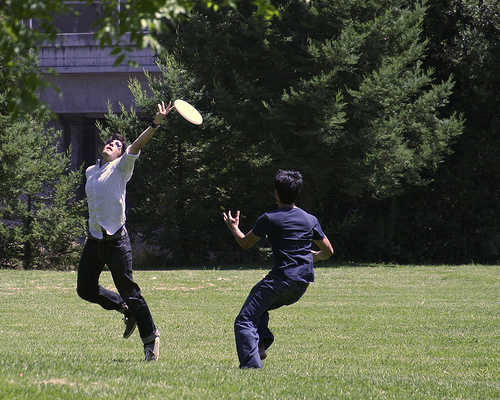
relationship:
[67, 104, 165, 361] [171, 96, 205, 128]
man about to catch a frisbee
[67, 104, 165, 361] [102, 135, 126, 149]
man wearing sunglasses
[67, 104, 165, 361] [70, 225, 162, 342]
man wearing pants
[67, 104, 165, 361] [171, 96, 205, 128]
man playing frisbee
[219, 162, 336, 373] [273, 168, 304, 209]
man with black hair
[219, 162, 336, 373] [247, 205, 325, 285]
man wearing a black shirt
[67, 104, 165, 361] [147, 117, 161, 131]
man wearing a black watch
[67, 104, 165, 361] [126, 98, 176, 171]
man with h arm extended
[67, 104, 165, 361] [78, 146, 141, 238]
man wearing a long sleeve shirt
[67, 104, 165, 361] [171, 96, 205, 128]
man reaching for a frisbee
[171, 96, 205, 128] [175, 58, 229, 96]
frisbee in air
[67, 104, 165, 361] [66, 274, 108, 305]
man knee bent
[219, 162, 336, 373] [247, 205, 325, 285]
man wearing a short sleeve shirt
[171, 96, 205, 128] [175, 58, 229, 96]
disc in air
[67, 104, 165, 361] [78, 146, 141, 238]
man wearing a white shirt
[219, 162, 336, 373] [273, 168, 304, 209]
man has dark hair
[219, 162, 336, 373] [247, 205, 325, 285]
man wearing a blue shirt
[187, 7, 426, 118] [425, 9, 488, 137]
trees in background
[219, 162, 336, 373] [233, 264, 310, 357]
man wearing jeans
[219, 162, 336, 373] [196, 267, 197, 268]
man in foreground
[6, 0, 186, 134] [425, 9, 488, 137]
building in background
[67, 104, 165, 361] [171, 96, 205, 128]
man catching a frisbee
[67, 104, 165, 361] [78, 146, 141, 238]
man wearing a shirt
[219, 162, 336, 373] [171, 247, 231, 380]
man runs in a field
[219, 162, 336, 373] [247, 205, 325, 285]
man wearing a t shirt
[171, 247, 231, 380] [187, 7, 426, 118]
field with trees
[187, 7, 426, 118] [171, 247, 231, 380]
trees in a field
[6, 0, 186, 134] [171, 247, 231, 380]
building next to a field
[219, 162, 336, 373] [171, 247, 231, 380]
man in a field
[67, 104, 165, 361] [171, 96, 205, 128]
man trying to catch a frisbee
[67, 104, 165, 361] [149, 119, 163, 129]
man wearing wrist watch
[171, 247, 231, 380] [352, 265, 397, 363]
field of green grass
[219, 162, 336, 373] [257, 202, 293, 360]
man wearing blue clothes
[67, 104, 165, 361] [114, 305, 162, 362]
man wearing brown shoes